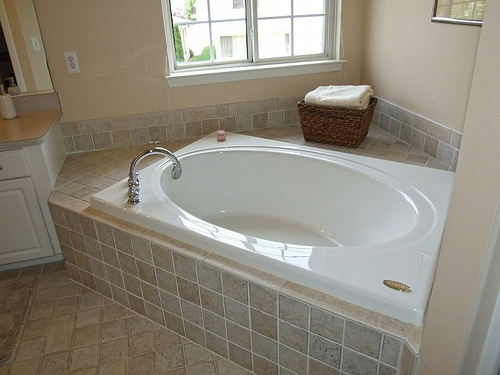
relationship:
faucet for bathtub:
[129, 145, 182, 203] [88, 130, 455, 326]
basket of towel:
[299, 97, 375, 147] [304, 83, 373, 109]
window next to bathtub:
[165, 2, 334, 69] [88, 130, 455, 326]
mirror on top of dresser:
[0, 23, 20, 88] [2, 114, 62, 269]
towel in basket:
[304, 83, 373, 109] [299, 97, 375, 147]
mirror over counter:
[0, 23, 20, 88] [1, 110, 62, 145]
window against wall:
[165, 2, 334, 69] [36, 1, 371, 122]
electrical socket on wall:
[64, 52, 83, 74] [36, 1, 371, 122]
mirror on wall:
[0, 23, 20, 88] [36, 1, 371, 122]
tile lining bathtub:
[200, 287, 224, 313] [88, 130, 455, 326]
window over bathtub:
[165, 2, 334, 69] [88, 130, 455, 326]